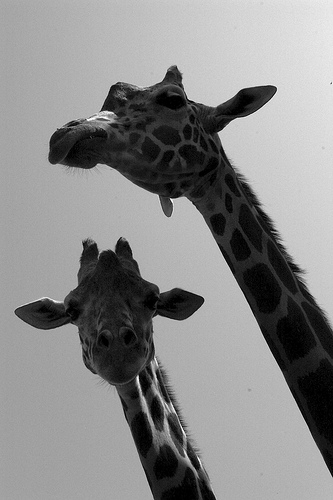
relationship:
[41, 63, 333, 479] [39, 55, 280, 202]
animal has head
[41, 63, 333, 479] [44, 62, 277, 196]
animal has head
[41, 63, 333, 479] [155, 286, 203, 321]
animal has ear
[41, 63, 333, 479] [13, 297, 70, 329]
animal has ear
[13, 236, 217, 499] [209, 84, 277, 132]
animal has ear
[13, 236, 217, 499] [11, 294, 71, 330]
animal has ear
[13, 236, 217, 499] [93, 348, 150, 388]
animal has mouth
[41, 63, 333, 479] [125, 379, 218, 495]
animal has neck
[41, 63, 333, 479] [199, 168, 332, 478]
animal has neck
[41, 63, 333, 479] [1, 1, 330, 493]
animal in photo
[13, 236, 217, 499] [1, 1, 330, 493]
animal in photo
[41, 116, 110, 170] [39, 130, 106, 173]
animal has mouth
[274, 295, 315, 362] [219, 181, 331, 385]
spot on neck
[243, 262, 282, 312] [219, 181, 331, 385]
spot on neck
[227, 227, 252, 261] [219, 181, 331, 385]
spot on neck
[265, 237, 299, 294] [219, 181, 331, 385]
spot on neck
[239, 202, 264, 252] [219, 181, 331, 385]
spot on neck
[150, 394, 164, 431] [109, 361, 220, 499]
spot on neck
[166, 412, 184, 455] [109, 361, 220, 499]
spot on neck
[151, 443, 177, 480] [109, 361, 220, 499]
spot on neck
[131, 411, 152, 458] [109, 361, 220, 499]
spot on neck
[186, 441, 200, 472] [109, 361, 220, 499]
spot on neck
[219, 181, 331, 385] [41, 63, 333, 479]
neck of animal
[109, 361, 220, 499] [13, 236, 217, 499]
neck of animal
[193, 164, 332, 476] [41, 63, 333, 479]
neck of animal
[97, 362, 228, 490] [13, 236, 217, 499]
neck of animal